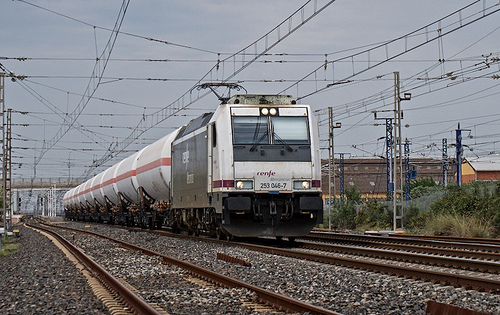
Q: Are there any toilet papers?
A: No, there are no toilet papers.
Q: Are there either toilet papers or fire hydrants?
A: No, there are no toilet papers or fire hydrants.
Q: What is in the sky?
A: The wires are in the sky.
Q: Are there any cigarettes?
A: No, there are no cigarettes.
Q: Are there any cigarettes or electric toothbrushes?
A: No, there are no cigarettes or electric toothbrushes.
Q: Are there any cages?
A: No, there are no cages.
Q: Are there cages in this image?
A: No, there are no cages.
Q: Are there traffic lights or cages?
A: No, there are no cages or traffic lights.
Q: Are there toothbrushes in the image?
A: No, there are no toothbrushes.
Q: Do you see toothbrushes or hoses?
A: No, there are no toothbrushes or hoses.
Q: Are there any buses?
A: No, there are no buses.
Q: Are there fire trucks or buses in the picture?
A: No, there are no buses or fire trucks.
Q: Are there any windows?
A: Yes, there is a window.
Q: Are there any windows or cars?
A: Yes, there is a window.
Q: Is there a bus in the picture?
A: No, there are no buses.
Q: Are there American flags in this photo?
A: No, there are no American flags.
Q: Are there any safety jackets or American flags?
A: No, there are no American flags or safety jackets.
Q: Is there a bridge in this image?
A: Yes, there is a bridge.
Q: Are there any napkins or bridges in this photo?
A: Yes, there is a bridge.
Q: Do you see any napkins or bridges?
A: Yes, there is a bridge.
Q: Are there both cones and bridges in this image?
A: No, there is a bridge but no cones.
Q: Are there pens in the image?
A: No, there are no pens.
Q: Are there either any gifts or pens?
A: No, there are no pens or gifts.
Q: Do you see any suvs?
A: No, there are no suvs.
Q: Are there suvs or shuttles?
A: No, there are no suvs or shuttles.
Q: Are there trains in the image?
A: Yes, there is a train.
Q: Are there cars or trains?
A: Yes, there is a train.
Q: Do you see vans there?
A: No, there are no vans.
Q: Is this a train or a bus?
A: This is a train.